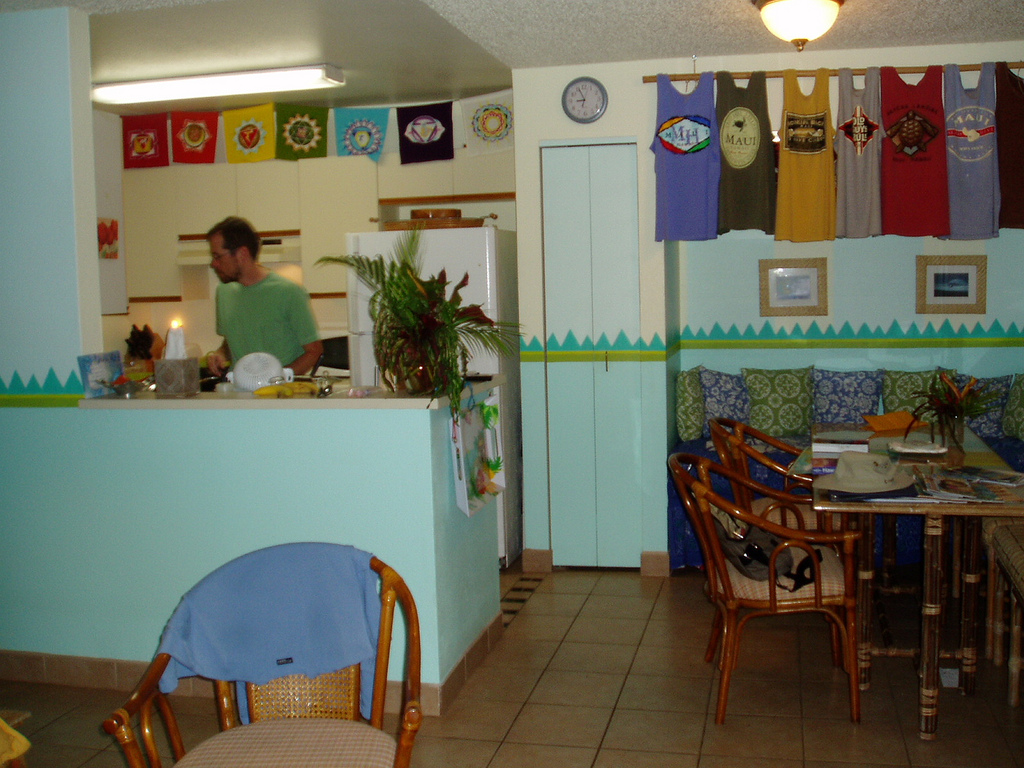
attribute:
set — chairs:
[662, 409, 889, 723]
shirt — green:
[205, 270, 316, 374]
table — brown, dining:
[805, 420, 1019, 740]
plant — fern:
[310, 219, 509, 418]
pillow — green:
[668, 364, 708, 449]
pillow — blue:
[699, 367, 743, 420]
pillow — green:
[740, 358, 818, 443]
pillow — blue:
[818, 367, 888, 426]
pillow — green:
[880, 369, 935, 417]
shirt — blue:
[143, 539, 383, 717]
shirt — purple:
[645, 70, 726, 245]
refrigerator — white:
[344, 220, 522, 573]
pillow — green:
[673, 362, 706, 443]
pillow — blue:
[699, 364, 747, 423]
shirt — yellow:
[768, 62, 838, 240]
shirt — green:
[211, 273, 318, 362]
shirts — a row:
[643, 67, 991, 236]